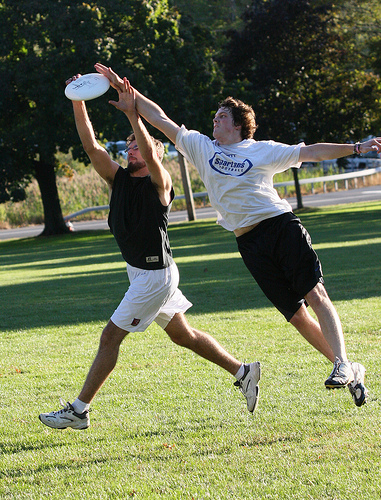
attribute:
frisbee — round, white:
[63, 69, 114, 104]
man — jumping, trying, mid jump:
[40, 62, 263, 434]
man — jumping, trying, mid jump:
[91, 62, 381, 407]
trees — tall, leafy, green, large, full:
[4, 0, 379, 249]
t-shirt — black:
[106, 164, 173, 269]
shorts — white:
[108, 258, 194, 335]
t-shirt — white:
[179, 127, 311, 249]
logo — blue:
[211, 148, 254, 180]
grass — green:
[4, 197, 381, 491]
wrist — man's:
[351, 143, 365, 155]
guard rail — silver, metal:
[64, 155, 380, 232]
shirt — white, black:
[170, 130, 304, 233]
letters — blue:
[207, 150, 255, 175]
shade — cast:
[6, 199, 379, 334]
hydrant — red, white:
[66, 223, 76, 234]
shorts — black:
[232, 219, 327, 324]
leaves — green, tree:
[4, 0, 380, 206]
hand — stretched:
[96, 58, 121, 88]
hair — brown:
[220, 93, 256, 141]